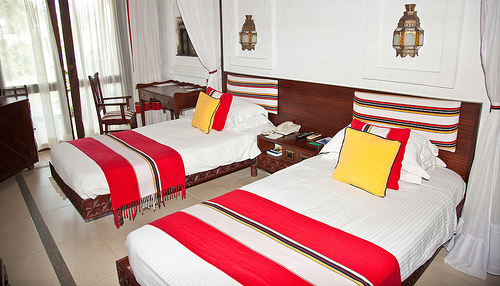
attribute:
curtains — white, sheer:
[10, 19, 61, 121]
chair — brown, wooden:
[84, 80, 125, 121]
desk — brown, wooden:
[140, 78, 187, 120]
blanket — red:
[94, 127, 163, 208]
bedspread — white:
[303, 165, 440, 284]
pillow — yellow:
[349, 124, 391, 193]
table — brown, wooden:
[254, 140, 292, 168]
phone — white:
[275, 121, 304, 138]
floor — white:
[8, 219, 47, 284]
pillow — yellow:
[196, 89, 214, 134]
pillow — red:
[218, 89, 233, 128]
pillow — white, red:
[371, 122, 412, 139]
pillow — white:
[238, 104, 266, 130]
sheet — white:
[449, 175, 466, 204]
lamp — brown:
[388, 20, 444, 76]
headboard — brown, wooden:
[272, 81, 350, 141]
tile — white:
[77, 239, 96, 276]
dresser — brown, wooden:
[1, 92, 32, 175]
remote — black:
[298, 126, 309, 142]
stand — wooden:
[256, 122, 291, 176]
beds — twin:
[76, 106, 394, 284]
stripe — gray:
[18, 176, 57, 272]